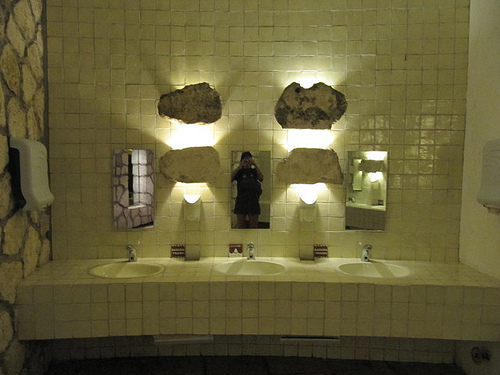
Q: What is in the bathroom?
A: Tiled wall.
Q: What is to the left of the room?
A: Rock wall.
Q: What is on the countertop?
A: Three sinks.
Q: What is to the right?
A: White stucco wall.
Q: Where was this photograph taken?
A: A public bathroom.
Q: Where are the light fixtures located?
A: On wall above sink.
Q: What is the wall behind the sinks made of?
A: White tiles.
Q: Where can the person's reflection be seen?
A: In the middle mirror.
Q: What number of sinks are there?
A: 3.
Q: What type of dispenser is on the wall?
A: Paper towel.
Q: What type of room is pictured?
A: Bathroom.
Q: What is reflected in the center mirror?
A: Person taking the photograph.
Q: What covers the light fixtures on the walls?
A: Rocks.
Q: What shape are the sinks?
A: Round.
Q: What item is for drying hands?
A: Paper towels.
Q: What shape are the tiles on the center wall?
A: Square.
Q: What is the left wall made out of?
A: Rocks.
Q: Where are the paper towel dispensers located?
A: On the left and right walls.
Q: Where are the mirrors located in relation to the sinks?
A: Above the sinks.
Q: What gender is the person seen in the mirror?
A: Female.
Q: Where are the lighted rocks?
A: The bathroom.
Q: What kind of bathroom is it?
A: Public.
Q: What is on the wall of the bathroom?
A: Three small mirrors.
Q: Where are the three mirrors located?
A: The wall.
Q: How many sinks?
A: 3.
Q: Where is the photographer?
A: Middle mirror.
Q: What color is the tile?
A: White.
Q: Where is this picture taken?
A: Bathroom.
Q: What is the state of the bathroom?
A: Clean.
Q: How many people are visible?
A: 1.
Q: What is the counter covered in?
A: Tile.